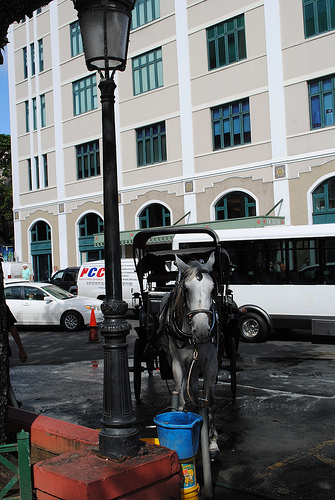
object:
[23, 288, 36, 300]
person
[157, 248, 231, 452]
horse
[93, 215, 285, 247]
awning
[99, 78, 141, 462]
lamp post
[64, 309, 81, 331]
tire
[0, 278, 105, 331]
car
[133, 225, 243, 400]
black carriage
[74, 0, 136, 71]
fancy light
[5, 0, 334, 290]
building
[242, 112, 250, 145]
windows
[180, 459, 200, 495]
bucket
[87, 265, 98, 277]
letter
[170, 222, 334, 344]
white bus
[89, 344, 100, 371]
reflection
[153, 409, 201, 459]
blue bucket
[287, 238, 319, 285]
windows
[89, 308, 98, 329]
cone